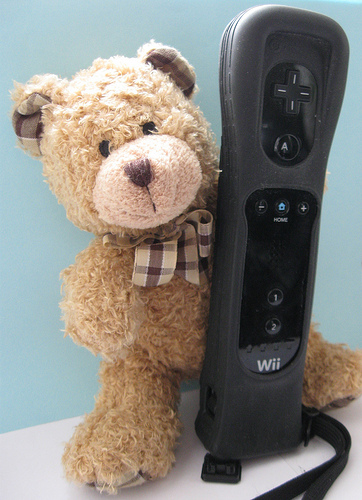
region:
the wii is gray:
[246, 354, 295, 377]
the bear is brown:
[25, 130, 205, 480]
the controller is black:
[201, 9, 328, 474]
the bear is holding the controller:
[8, 14, 352, 496]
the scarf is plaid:
[118, 235, 209, 286]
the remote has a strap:
[211, 3, 350, 495]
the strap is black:
[275, 471, 356, 497]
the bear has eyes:
[91, 126, 178, 156]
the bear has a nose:
[118, 157, 162, 186]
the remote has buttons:
[255, 280, 290, 343]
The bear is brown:
[25, 62, 214, 289]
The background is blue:
[2, 364, 69, 418]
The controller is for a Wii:
[246, 347, 284, 384]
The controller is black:
[203, 134, 305, 321]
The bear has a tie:
[70, 213, 259, 292]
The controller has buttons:
[211, 168, 307, 368]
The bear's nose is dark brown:
[121, 155, 159, 203]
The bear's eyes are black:
[131, 117, 168, 140]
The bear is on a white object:
[17, 417, 263, 497]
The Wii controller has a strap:
[207, 387, 351, 495]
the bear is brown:
[5, 42, 318, 487]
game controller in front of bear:
[176, 5, 342, 477]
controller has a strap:
[246, 392, 355, 495]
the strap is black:
[264, 396, 354, 494]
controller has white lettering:
[244, 345, 284, 380]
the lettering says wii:
[249, 349, 296, 382]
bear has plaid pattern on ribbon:
[112, 206, 219, 311]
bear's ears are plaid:
[13, 66, 63, 165]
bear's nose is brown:
[110, 144, 176, 202]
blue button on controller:
[268, 194, 290, 219]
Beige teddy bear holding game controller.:
[11, 20, 350, 490]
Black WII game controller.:
[197, 7, 361, 479]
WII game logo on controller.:
[253, 355, 293, 373]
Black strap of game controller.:
[254, 404, 355, 498]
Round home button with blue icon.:
[274, 192, 291, 219]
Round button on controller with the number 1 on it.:
[261, 280, 290, 314]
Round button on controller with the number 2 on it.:
[266, 314, 281, 337]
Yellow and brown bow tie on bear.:
[121, 210, 228, 288]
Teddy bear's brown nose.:
[124, 152, 159, 198]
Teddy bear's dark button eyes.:
[94, 122, 175, 160]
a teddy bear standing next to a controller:
[13, 40, 361, 489]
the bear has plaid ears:
[13, 39, 195, 143]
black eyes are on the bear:
[91, 115, 164, 155]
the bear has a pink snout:
[89, 133, 200, 229]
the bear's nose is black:
[125, 157, 155, 188]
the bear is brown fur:
[18, 46, 353, 499]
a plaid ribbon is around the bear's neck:
[103, 209, 218, 293]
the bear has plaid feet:
[87, 471, 154, 488]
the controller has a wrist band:
[239, 402, 356, 497]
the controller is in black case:
[198, 5, 316, 468]